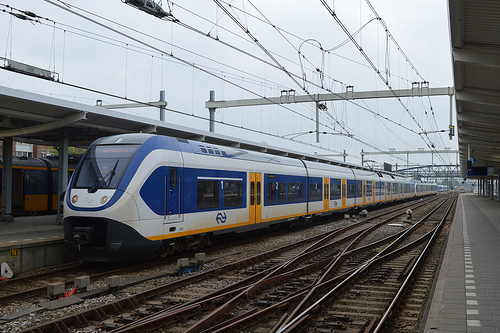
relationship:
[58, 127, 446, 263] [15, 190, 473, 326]
train on track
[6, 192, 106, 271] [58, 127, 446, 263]
platform near train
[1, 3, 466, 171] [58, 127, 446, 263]
wires above train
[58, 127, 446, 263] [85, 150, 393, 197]
train has windows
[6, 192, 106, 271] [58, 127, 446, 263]
platform next to train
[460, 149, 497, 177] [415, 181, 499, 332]
sign above platform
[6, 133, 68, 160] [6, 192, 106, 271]
building behind platform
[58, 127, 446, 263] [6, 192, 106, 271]
train at platform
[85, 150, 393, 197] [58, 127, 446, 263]
windows on train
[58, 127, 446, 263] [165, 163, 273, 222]
train has door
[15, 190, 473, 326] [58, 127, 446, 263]
track under train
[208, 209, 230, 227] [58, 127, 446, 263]
logo on train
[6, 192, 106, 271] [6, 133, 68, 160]
platform near building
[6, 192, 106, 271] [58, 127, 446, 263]
platform above train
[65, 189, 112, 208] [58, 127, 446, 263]
lights on train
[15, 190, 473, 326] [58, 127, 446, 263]
track underneath train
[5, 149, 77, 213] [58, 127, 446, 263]
train besides train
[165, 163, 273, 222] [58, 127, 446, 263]
door on train